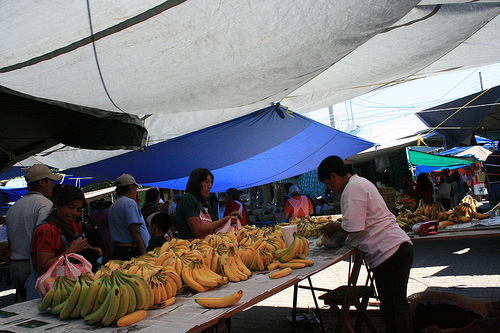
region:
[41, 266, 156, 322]
green bananas on a table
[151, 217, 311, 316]
several yellow bananas on a table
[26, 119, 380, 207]
a blue tarp hanging over a market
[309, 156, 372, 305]
a woman wearing a white shirt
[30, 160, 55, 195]
a man wearing a cap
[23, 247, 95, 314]
a pink and white plastic bag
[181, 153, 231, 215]
a man with black hair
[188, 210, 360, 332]
a long wood table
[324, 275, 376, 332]
a wood stool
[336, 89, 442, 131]
electrical wires attached to poles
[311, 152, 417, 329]
person dressed in white top and black bottom inspecting bananas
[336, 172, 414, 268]
white top of the person inspecting bananas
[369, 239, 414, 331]
black bottoms of person inspecting bananas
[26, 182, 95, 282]
woman at the front of the table on left side looking at bananas and smiling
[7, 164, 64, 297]
man dressed in jeans white shirt and white cap behind smiling woman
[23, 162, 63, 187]
white cap of the man behind smiling woman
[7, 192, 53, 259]
white shirt of the man behind smiling woman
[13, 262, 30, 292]
jeans of the man in white shirt behind smling woman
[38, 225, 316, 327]
table full of bananas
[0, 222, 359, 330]
table holding bananas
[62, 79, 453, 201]
blue canopy over people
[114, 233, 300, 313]
yellow bananas on table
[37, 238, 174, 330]
green and yellow bananas on table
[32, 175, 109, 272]
person wearing red shirt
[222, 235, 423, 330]
small wood seat under table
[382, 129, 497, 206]
green canopy over people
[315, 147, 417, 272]
person wearing white shirt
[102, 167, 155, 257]
guy wearing cap and belt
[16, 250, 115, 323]
red and white bag on table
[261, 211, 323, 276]
white styrofoam cup on table with bananas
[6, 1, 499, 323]
an open air market has canapies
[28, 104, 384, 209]
a blue tarp is over the customers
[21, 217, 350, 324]
hands of bananas are on the table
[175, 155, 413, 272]
a customer is buying bananas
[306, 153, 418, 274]
the seller is wrapping up a purchase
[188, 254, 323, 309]
single bananas are for sale on the table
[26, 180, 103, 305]
a lady has a shopping bag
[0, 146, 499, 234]
potential customers are walking under the tarps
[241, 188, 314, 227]
baskets of products are near the lady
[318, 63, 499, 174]
wooden poles with wires are above the market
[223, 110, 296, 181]
Blue tarp hanging over the peoples heads.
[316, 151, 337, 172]
Person has dark hair.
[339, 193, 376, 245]
Person wearing white shirt.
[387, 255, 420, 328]
Person wearing dark pants.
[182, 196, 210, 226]
Person wearing green shirt.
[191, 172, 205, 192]
Person has dark hair.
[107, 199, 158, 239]
Person wearing blue shirt.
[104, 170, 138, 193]
Person wearing tan hat.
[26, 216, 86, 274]
Person wearing red shirt.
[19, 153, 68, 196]
Person wearing tan hat.